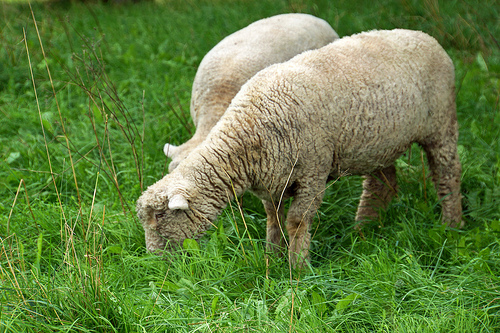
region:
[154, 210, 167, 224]
EYE OF WOOLY SHEEP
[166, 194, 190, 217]
EAR OF WOOLY SHEEP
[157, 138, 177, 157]
EAR OF WOOLY SHEEP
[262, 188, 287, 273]
LEG OF WOOLY SHEEP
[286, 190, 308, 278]
LEG OF WOOLY SHEEP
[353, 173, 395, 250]
LEG OF WOOLY SHEEP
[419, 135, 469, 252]
LEG OF WOOLY SHEEP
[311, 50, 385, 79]
BACK OF WOOLY SHEEP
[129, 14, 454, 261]
two sheep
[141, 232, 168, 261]
the sheep is eating the grass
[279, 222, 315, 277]
front leg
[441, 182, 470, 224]
back leg of the sheep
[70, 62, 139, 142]
branches in the grass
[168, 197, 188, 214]
ear of the sheep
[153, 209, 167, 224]
the sheeps eye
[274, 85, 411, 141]
the sheeps fur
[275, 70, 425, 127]
the fur is white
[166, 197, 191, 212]
ear of a sheep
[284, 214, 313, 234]
brown spot of fur on the sheep's knee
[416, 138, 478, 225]
back left leg of the sheep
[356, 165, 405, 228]
back right leg of a sheep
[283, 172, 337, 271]
front left leg of the sheep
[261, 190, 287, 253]
front right leg of a sheep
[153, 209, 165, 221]
front left eye of the sheep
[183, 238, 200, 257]
leaf of a plant growing in the grass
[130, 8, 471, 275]
two sheep grazing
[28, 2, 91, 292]
a tall brown thin plant growing in the grass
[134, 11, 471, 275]
two sheep stand next to each other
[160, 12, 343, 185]
sheep is behind other sheep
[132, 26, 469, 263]
sheep is in front of other sheep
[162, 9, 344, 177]
sheep eats grass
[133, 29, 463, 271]
sheep eats grass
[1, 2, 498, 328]
grass is being eaten by sheep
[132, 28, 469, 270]
sheep stands still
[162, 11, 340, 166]
sheep stands still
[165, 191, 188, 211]
ear is attached to sheep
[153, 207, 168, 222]
eye is attached to sheep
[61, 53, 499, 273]
sheep in a field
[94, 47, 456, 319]
two sheep in a field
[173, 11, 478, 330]
sheep standing in a field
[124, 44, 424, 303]
two sheep standing in a field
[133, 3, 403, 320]
sheep eatting in a field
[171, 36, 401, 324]
two sheep eatting in a field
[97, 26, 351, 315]
sheep eatting the grass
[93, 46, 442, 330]
two sheep eatting grass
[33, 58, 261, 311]
a field of grass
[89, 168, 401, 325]
a field of green grass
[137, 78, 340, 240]
an animal in a field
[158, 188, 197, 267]
an ear on the animal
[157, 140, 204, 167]
an ear on the animal